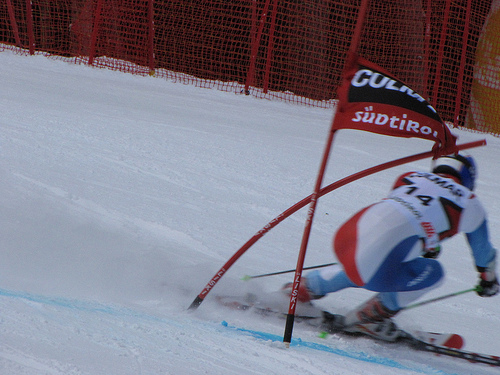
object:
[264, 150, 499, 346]
person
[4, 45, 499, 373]
slope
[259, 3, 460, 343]
ski flag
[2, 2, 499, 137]
mesh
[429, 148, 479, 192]
head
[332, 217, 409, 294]
back side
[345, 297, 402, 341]
right shoe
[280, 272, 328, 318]
left shoe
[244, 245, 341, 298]
left ski pole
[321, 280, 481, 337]
right ski pole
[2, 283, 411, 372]
line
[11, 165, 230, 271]
track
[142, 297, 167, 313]
hole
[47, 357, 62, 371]
hole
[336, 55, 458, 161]
flag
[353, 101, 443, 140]
word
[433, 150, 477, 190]
helmet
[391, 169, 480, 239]
back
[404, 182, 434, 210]
number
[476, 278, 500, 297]
hand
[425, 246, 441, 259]
hand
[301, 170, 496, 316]
uniform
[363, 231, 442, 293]
design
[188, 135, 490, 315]
pole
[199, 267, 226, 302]
letters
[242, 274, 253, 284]
tip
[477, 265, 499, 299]
glove